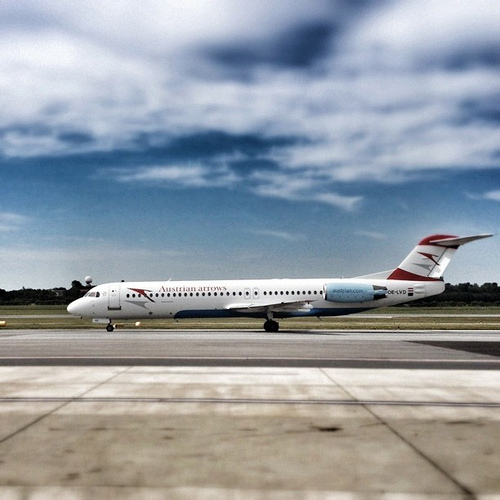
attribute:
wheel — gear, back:
[253, 310, 278, 329]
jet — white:
[54, 220, 466, 364]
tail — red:
[409, 210, 473, 283]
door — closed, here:
[99, 285, 136, 310]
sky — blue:
[46, 90, 343, 230]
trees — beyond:
[3, 278, 94, 310]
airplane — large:
[104, 239, 242, 329]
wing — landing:
[225, 293, 349, 351]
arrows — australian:
[395, 241, 447, 277]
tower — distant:
[72, 258, 118, 305]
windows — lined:
[156, 261, 290, 315]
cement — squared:
[122, 362, 499, 495]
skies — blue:
[64, 47, 498, 253]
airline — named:
[366, 239, 438, 298]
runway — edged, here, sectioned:
[73, 315, 493, 398]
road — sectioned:
[360, 348, 482, 383]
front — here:
[59, 220, 150, 335]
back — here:
[307, 271, 467, 380]